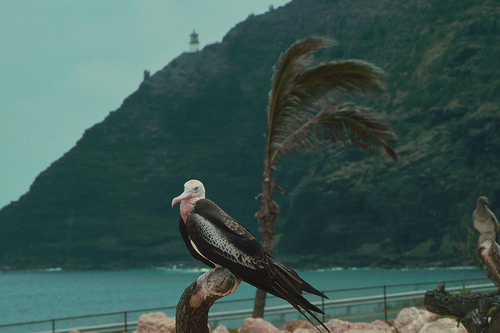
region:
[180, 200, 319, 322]
bird's feathers are black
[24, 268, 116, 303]
the water is blue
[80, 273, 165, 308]
the water is blue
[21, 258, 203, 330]
the water is blue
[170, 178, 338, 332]
A bird perched on a tree stump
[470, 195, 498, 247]
A bird perched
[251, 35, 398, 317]
A palm tree blowing in the wind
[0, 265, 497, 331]
Crystal blue water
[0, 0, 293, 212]
Blue partly cloudy sky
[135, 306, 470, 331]
A pile of pinkish looking rocks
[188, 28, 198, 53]
A lighthouse up on a bluff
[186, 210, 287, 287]
A black and white speckled wing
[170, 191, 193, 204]
An orange narrow beak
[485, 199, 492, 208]
A black narrow beak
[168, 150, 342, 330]
Black, red, and white bird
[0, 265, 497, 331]
Body of water behind the bird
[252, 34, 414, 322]
Palm tree blowing in the breeze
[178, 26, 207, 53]
Lighthouse on a cliff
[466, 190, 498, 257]
Brown, black, and white bird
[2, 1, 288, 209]
Clear blue sky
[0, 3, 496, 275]
Cliff covered in vegetation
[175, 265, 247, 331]
Wood perch bird is standing on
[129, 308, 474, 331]
Light colored rocks behind perch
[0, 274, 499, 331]
Metal, gray guard rail